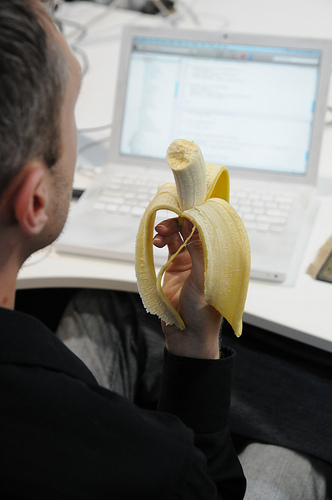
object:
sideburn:
[41, 91, 66, 169]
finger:
[155, 216, 179, 236]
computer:
[96, 12, 328, 285]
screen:
[123, 56, 314, 168]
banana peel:
[206, 161, 229, 198]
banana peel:
[180, 197, 250, 337]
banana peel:
[134, 184, 177, 312]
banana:
[164, 135, 207, 210]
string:
[154, 223, 200, 291]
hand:
[153, 205, 227, 355]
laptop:
[54, 24, 329, 285]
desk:
[14, 0, 332, 365]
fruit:
[164, 137, 208, 210]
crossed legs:
[58, 292, 332, 500]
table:
[25, 248, 331, 339]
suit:
[0, 300, 332, 500]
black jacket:
[0, 310, 249, 499]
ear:
[14, 167, 48, 237]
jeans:
[52, 287, 331, 497]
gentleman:
[0, 3, 330, 499]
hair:
[2, 0, 66, 187]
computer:
[55, 21, 332, 282]